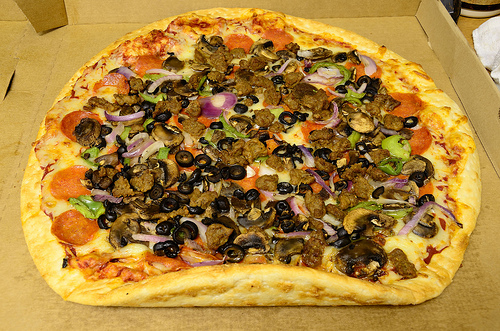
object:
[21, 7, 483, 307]
food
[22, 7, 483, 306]
pizza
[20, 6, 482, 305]
design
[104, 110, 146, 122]
onion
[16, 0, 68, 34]
part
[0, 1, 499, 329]
box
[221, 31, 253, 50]
pieces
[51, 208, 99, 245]
pepperoni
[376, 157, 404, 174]
peppers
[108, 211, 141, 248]
mushrooms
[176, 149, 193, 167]
olive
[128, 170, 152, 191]
steakball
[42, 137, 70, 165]
mozzarella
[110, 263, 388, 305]
crust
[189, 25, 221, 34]
spices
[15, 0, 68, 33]
cardboard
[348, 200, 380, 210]
leaf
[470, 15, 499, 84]
towel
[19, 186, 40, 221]
edge